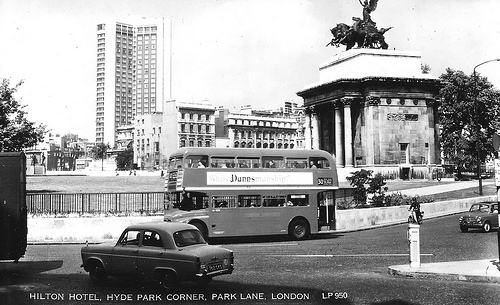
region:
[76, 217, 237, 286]
Small car in front of the camera.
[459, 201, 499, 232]
Small car on the right side of the photo.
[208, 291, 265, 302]
The words PARK LANE.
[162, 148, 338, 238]
A double decker bus.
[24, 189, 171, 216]
Railing between buses on the road.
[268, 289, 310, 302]
The word LONDON.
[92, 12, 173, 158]
An extremely tall building with lots of windows.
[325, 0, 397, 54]
A statue on top of a building on the top right.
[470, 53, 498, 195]
A light pole on the far right.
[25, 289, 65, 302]
The word Hilton.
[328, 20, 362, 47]
Dark sculpture of horses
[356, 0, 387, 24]
Sculpture of angel riding a chariot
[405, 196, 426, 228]
Person riding a bicycle on a street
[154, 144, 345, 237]
Double decker bus on a street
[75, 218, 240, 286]
Car going left on a street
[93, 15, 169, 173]
Large building behind a street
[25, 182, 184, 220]
Fence behind a street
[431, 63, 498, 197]
Tree with leaves lining a street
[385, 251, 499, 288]
White curb next to street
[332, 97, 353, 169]
Pillars of a monument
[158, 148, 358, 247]
Double decker bus on road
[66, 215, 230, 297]
Car turning in front of bus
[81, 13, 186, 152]
Tall white building in background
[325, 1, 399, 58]
Large statue on building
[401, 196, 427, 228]
Man riding a motorcycle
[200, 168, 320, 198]
White sign on side of bus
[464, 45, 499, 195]
Black light post near road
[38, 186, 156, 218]
Iron fence surrounding field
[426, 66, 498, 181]
Full tree on right side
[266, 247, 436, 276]
White line on road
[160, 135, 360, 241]
a double-decker bus on a road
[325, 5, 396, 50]
a statue on a building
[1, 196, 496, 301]
a busy road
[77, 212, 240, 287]
a car on a road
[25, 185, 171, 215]
an iron railing alongside a road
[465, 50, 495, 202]
a tall streetlight next to a road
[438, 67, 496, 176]
a large leafy tree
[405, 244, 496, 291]
a sidewalk beside a road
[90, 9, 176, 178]
a tall white building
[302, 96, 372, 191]
columns on a building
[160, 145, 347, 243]
double decker bus filled with people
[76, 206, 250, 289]
old fashioned car in mid-turn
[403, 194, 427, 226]
person on a bike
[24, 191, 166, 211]
tiny grated fence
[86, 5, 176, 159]
tall building with a lot of windows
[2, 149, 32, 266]
back of a vehicle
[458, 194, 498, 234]
front half of a tiny car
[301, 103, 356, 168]
four stone pillars on the front of the building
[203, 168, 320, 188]
white rectangle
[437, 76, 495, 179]
tree